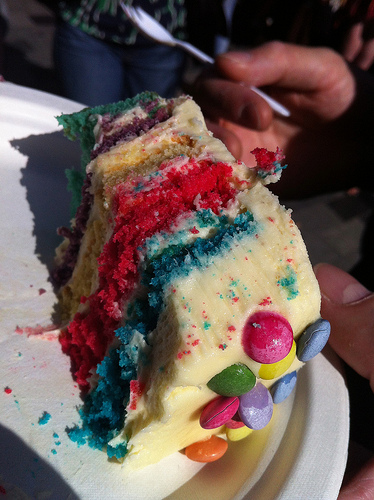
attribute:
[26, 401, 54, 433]
crump cake — blue